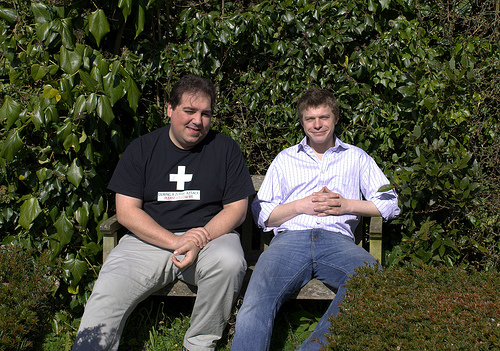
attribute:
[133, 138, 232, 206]
shirt — black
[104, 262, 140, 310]
jeans — light grey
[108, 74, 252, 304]
man — smiling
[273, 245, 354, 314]
jeans — blue, faded, light blue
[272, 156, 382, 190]
shirt — white, striped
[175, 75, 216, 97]
hair — short, dark, black, brown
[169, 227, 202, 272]
hands — folded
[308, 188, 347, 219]
fingers — crossed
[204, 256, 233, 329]
pants — gray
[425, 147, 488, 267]
shrubs — green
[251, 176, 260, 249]
bench — green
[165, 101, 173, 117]
ear — white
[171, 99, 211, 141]
face — pudgy, white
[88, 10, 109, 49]
leaf — pointy, green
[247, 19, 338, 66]
bush — green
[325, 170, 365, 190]
stripes — blue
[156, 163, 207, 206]
logo — white